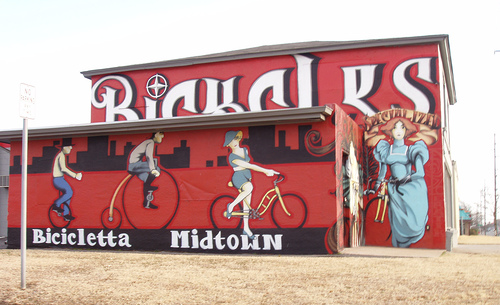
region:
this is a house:
[1, 32, 456, 253]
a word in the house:
[162, 226, 287, 258]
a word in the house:
[25, 220, 126, 260]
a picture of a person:
[211, 129, 279, 247]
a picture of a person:
[122, 134, 167, 211]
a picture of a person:
[47, 139, 84, 225]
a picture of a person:
[362, 93, 439, 253]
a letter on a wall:
[322, 51, 381, 133]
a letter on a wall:
[237, 63, 290, 114]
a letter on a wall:
[87, 69, 142, 127]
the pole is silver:
[9, 71, 35, 298]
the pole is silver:
[7, 71, 72, 294]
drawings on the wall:
[9, 105, 360, 302]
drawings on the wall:
[96, 48, 446, 303]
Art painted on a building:
[17, 45, 412, 294]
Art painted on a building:
[324, 104, 444, 281]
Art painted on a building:
[211, 110, 297, 253]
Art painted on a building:
[112, 123, 209, 256]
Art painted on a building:
[33, 127, 95, 244]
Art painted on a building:
[40, 89, 123, 245]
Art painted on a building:
[96, 39, 262, 254]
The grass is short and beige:
[75, 268, 438, 299]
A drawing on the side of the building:
[22, 130, 324, 255]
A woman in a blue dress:
[363, 112, 433, 250]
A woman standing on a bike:
[211, 126, 313, 246]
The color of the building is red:
[52, 136, 292, 238]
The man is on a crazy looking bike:
[95, 129, 193, 246]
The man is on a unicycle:
[28, 135, 100, 242]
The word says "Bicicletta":
[31, 222, 139, 255]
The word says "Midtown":
[165, 222, 287, 256]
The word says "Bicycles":
[86, 44, 440, 124]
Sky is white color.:
[9, 23, 114, 73]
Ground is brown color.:
[73, 265, 214, 303]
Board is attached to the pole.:
[11, 69, 48, 276]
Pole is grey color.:
[11, 119, 62, 289]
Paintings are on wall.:
[46, 89, 438, 256]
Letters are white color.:
[51, 74, 406, 271]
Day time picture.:
[5, 11, 474, 283]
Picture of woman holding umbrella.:
[358, 95, 436, 220]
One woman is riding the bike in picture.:
[201, 135, 296, 242]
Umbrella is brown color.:
[366, 102, 456, 173]